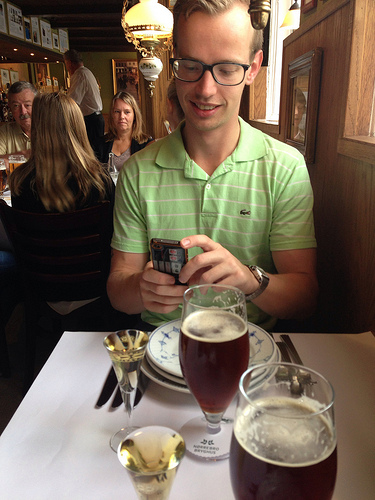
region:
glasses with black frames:
[167, 57, 249, 87]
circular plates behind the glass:
[139, 310, 283, 397]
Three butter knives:
[97, 330, 148, 411]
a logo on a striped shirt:
[239, 205, 252, 219]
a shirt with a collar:
[113, 136, 317, 331]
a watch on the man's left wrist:
[237, 264, 271, 299]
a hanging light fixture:
[122, 0, 171, 98]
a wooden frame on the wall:
[281, 52, 321, 164]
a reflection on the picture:
[292, 85, 304, 137]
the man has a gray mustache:
[6, 82, 36, 128]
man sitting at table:
[146, 7, 353, 487]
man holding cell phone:
[104, 198, 257, 339]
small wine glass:
[86, 323, 178, 448]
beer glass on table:
[152, 269, 268, 469]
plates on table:
[137, 304, 326, 410]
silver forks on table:
[263, 326, 319, 414]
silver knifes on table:
[90, 326, 159, 435]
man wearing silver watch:
[242, 245, 283, 321]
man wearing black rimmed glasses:
[143, 33, 275, 98]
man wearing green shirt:
[127, 90, 325, 346]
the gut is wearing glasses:
[163, 49, 248, 90]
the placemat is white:
[35, 396, 86, 474]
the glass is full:
[164, 281, 248, 434]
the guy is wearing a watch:
[244, 257, 272, 299]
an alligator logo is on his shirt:
[235, 203, 255, 224]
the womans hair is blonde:
[33, 103, 80, 154]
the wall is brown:
[331, 168, 362, 236]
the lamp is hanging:
[112, 1, 171, 89]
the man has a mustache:
[15, 109, 31, 120]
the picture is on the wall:
[279, 50, 332, 158]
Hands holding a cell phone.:
[140, 226, 198, 303]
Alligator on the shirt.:
[233, 205, 254, 218]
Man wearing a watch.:
[235, 260, 271, 309]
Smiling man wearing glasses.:
[166, 58, 252, 87]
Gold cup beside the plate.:
[100, 324, 153, 431]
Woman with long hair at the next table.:
[25, 75, 98, 208]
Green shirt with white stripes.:
[129, 175, 189, 227]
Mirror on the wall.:
[272, 52, 330, 146]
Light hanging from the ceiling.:
[121, 2, 170, 95]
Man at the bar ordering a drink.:
[56, 33, 103, 113]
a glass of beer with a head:
[173, 290, 245, 411]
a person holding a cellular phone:
[137, 228, 238, 279]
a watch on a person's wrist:
[242, 257, 273, 299]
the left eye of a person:
[216, 65, 241, 78]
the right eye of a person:
[183, 60, 200, 72]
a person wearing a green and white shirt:
[99, 105, 336, 243]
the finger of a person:
[179, 233, 214, 249]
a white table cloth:
[301, 330, 349, 365]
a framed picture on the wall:
[280, 58, 323, 153]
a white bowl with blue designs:
[154, 326, 175, 361]